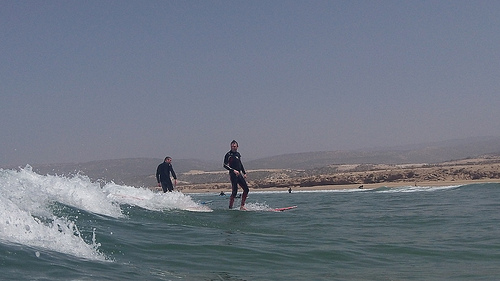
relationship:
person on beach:
[413, 180, 421, 189] [387, 179, 414, 187]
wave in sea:
[108, 180, 166, 213] [332, 192, 499, 240]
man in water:
[223, 139, 254, 212] [298, 190, 357, 233]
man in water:
[156, 154, 183, 191] [298, 190, 357, 233]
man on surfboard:
[223, 139, 254, 212] [233, 202, 301, 214]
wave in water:
[108, 180, 166, 213] [298, 190, 357, 233]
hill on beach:
[341, 162, 397, 184] [387, 179, 414, 187]